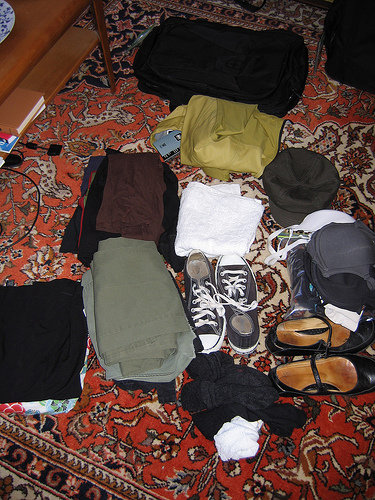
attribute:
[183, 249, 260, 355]
shoes — black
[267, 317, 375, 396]
dress shoes — flat, black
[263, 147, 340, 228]
hat — gray, black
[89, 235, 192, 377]
pants — green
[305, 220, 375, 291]
bra — dark, gray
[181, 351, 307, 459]
socks — dark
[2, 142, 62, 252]
cord — black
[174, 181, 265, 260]
towel — folded, white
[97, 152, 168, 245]
shirt — folded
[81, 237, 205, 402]
pants — folded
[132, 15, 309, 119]
bag — black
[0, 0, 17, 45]
dish — blue, white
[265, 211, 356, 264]
bra — white